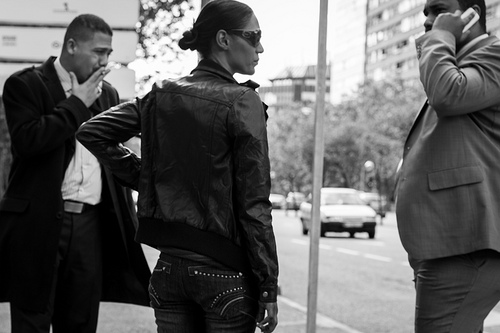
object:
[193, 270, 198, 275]
studs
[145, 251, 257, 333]
pants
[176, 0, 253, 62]
hair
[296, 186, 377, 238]
car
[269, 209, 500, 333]
road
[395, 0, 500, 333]
man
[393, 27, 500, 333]
business suit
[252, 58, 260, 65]
mouth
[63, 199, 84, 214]
belt clip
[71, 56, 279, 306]
jacket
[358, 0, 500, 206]
building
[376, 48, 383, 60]
windows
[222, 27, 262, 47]
sunglasses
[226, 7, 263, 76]
face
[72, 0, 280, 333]
woman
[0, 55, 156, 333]
coat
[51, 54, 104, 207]
shirt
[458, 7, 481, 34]
phone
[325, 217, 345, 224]
headlights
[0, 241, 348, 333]
sidewalk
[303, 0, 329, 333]
pole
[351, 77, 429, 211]
trees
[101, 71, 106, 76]
cigarette